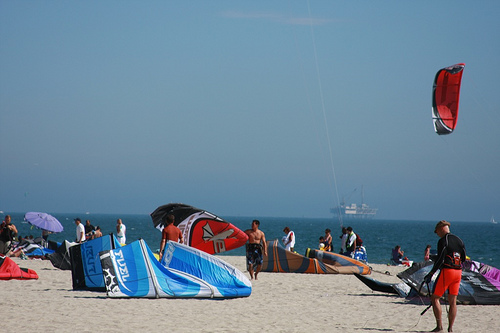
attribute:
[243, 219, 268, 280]
man — shirtless, bare chested, walking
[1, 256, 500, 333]
beach — sandy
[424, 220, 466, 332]
man — wind surfer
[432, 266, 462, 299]
shorts — tight, red, orange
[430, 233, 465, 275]
tee shirt — black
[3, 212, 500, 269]
ocean — blue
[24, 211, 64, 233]
umbrella — blue, lavender, purple, open, light purple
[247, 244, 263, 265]
shorts — black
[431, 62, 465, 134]
kite — orange, black, red, big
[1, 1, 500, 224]
sky — blue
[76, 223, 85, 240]
tee shirt — white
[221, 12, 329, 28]
cloud — small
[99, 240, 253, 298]
kite — blue, white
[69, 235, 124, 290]
kite — black, blue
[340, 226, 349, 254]
man — flying a kite